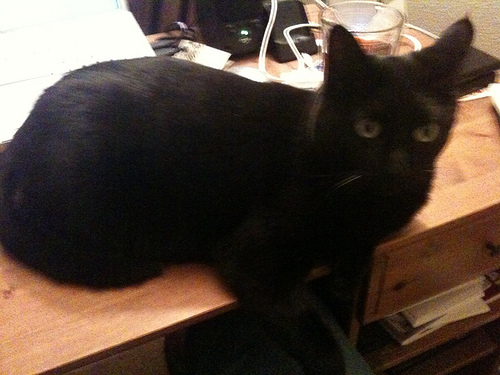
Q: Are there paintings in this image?
A: No, there are no paintings.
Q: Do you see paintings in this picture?
A: No, there are no paintings.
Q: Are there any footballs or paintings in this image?
A: No, there are no paintings or footballs.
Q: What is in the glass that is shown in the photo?
A: The liquid is in the glass.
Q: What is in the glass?
A: The liquid is in the glass.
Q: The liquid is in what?
A: The liquid is in the glass.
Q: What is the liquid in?
A: The liquid is in the glass.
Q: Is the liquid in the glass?
A: Yes, the liquid is in the glass.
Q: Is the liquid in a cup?
A: No, the liquid is in the glass.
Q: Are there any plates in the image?
A: No, there are no plates.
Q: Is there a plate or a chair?
A: No, there are no plates or chairs.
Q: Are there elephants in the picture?
A: No, there are no elephants.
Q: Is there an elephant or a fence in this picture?
A: No, there are no elephants or fences.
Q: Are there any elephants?
A: No, there are no elephants.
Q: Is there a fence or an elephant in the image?
A: No, there are no elephants or fences.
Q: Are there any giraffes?
A: No, there are no giraffes.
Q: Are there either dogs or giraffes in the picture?
A: No, there are no giraffes or dogs.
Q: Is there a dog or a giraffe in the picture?
A: No, there are no giraffes or dogs.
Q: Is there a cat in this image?
A: Yes, there is a cat.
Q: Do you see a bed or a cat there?
A: Yes, there is a cat.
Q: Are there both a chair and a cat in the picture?
A: No, there is a cat but no chairs.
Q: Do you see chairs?
A: No, there are no chairs.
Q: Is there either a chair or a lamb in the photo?
A: No, there are no chairs or lambs.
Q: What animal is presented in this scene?
A: The animal is a cat.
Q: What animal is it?
A: The animal is a cat.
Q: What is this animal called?
A: This is a cat.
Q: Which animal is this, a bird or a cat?
A: This is a cat.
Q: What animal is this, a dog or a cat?
A: This is a cat.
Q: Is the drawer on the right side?
A: Yes, the drawer is on the right of the image.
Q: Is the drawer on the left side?
A: No, the drawer is on the right of the image.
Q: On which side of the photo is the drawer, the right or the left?
A: The drawer is on the right of the image.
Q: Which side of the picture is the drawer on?
A: The drawer is on the right of the image.